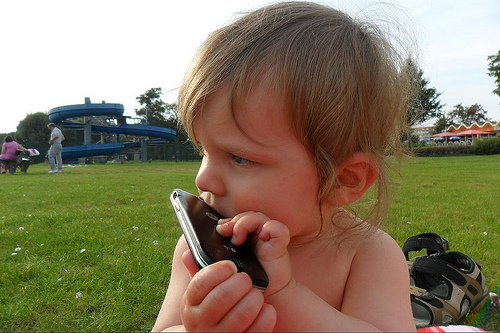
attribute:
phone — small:
[169, 174, 277, 292]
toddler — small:
[108, 21, 480, 331]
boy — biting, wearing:
[125, 33, 422, 294]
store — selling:
[389, 98, 494, 192]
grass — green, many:
[60, 212, 115, 250]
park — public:
[6, 151, 186, 281]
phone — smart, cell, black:
[153, 215, 319, 277]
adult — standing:
[33, 61, 105, 178]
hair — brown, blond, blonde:
[212, 3, 301, 64]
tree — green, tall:
[115, 46, 171, 129]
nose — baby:
[170, 144, 230, 194]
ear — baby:
[317, 125, 422, 209]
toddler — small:
[140, 17, 423, 307]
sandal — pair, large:
[370, 192, 476, 309]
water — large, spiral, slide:
[47, 134, 174, 184]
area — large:
[5, 167, 131, 253]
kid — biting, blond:
[166, 55, 373, 219]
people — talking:
[3, 111, 105, 172]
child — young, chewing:
[138, 61, 398, 256]